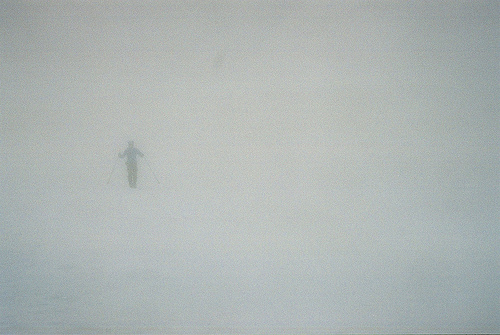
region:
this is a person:
[93, 117, 176, 201]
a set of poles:
[101, 140, 166, 196]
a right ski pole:
[132, 140, 163, 185]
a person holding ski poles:
[85, 126, 197, 224]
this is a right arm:
[136, 147, 147, 161]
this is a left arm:
[108, 137, 128, 167]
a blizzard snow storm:
[252, 165, 307, 212]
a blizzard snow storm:
[200, 242, 251, 279]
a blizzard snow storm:
[299, 268, 361, 318]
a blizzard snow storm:
[367, 182, 444, 241]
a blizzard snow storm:
[344, 34, 421, 77]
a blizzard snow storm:
[174, 33, 227, 71]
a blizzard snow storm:
[55, 45, 106, 80]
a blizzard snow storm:
[42, 108, 69, 163]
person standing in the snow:
[107, 125, 167, 210]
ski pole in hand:
[145, 157, 169, 186]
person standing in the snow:
[97, 122, 171, 199]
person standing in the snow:
[89, 137, 199, 222]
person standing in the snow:
[65, 127, 176, 219]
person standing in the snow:
[99, 135, 166, 208]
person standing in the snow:
[87, 124, 187, 210]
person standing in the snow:
[96, 127, 194, 227]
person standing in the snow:
[91, 127, 159, 208]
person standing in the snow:
[105, 133, 180, 209]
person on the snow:
[102, 138, 171, 192]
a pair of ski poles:
[95, 153, 177, 191]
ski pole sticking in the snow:
[141, 156, 166, 184]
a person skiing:
[92, 132, 169, 194]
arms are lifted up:
[111, 148, 151, 158]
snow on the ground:
[1, 0, 498, 333]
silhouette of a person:
[116, 135, 159, 191]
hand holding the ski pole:
[101, 147, 130, 184]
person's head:
[124, 138, 136, 147]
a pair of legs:
[123, 161, 146, 188]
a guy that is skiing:
[100, 125, 177, 201]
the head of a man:
[122, 135, 137, 150]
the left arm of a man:
[135, 150, 150, 160]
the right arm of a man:
[112, 145, 130, 157]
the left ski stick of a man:
[135, 156, 165, 182]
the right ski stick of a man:
[90, 157, 130, 180]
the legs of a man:
[125, 160, 146, 182]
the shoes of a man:
[118, 178, 143, 190]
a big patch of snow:
[113, 213, 318, 310]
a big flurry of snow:
[161, 21, 290, 141]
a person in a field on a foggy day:
[117, 141, 144, 189]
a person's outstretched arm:
[132, 148, 142, 159]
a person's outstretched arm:
[117, 150, 127, 157]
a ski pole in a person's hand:
[142, 153, 162, 185]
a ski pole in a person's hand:
[107, 156, 117, 186]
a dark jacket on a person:
[122, 142, 140, 168]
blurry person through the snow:
[119, 140, 147, 187]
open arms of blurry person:
[116, 148, 146, 163]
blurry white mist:
[3, 5, 490, 332]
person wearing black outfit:
[119, 138, 142, 189]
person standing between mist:
[114, 137, 144, 190]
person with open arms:
[116, 137, 146, 190]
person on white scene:
[117, 139, 145, 190]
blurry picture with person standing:
[0, 3, 495, 334]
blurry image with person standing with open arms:
[0, 2, 498, 334]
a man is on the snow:
[106, 129, 161, 198]